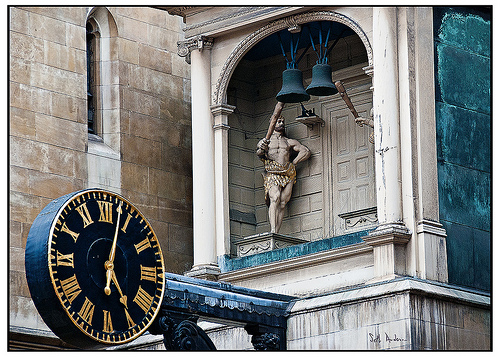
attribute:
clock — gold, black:
[25, 187, 165, 346]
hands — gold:
[104, 200, 129, 307]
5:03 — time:
[104, 197, 139, 329]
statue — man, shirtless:
[255, 100, 312, 233]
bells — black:
[274, 58, 338, 103]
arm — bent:
[287, 139, 311, 167]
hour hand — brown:
[106, 261, 129, 309]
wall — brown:
[10, 6, 193, 335]